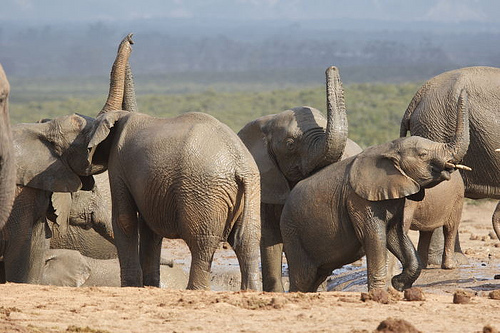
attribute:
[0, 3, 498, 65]
sky — blue 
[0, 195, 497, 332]
ground — brown 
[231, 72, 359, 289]
elephant — gray 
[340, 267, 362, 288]
water — puddle 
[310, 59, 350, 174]
trunk — raised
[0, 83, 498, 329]
field — flat , grassy , green 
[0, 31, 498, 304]
herd — elephants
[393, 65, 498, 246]
elephant — gray 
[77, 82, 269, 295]
elephant — gray 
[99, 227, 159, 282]
leg — front left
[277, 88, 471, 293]
elephant — small, grey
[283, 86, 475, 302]
small elephant — small 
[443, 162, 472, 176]
tusks — small 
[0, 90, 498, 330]
land — flat 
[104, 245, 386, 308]
hole — muddy 